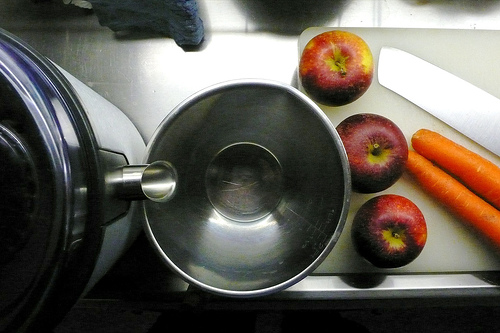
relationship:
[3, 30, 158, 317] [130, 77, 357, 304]
juicer above bowl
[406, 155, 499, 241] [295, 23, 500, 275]
carrot on a board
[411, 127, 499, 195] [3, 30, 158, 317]
carrot next to juicer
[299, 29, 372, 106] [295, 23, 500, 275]
apple on a board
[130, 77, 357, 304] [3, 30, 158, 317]
bowl below juicer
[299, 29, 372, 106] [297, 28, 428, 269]
apple in group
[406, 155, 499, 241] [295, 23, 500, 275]
carrot on board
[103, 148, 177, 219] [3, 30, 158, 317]
spout on juicer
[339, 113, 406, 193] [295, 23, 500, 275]
apple on board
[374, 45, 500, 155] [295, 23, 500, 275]
knife on board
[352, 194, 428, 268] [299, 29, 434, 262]
apple of three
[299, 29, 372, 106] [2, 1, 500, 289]
apple sitting on counter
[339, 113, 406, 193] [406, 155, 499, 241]
apple and carrot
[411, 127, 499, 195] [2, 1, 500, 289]
carrot on table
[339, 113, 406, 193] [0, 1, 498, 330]
apple in photo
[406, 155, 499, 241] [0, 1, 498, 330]
carrot in photo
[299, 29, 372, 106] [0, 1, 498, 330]
apple in photo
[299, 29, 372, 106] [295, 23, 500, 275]
apple on board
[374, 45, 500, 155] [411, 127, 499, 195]
knife near carrot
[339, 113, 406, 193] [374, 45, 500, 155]
apple near knife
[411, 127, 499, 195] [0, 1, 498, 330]
carrot in photo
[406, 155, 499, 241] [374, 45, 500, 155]
carrot next  to knife